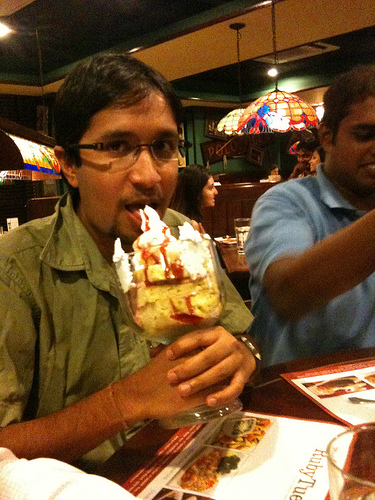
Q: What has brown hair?
A: The boy.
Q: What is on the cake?
A: Whipped cream.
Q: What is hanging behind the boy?
A: The lamps.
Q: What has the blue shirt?
A: The man.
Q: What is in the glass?
A: Ice cream.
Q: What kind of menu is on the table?
A: Hotel.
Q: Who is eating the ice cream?
A: Man with glasses.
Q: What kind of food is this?
A: Dessert.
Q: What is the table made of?
A: Wood.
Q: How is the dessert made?
A: With ice cream.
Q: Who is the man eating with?
A: A friend.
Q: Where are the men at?
A: A restaurant.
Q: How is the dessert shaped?
A: Upwards.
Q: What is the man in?
A: Blue shirt.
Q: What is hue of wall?
A: Green.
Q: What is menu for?
A: Restaurant.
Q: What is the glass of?
A: Dessert.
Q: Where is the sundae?
A: In cup.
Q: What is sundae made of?
A: Ice cream.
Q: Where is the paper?
A: On table.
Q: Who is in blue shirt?
A: A man.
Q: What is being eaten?
A: Sundae.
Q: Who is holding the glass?
A: A man.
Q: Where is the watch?
A: On the man's wrist.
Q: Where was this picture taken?
A: A restaurant.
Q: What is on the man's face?
A: Glasses.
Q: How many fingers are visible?
A: Four.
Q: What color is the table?
A: Brown.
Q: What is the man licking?
A: Whipped cream.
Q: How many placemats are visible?
A: Two.